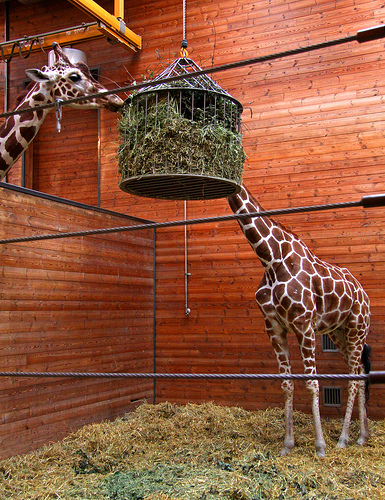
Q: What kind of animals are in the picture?
A: Giraffes.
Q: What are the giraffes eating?
A: Hay.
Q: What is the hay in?
A: A cage.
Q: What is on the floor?
A: Hay.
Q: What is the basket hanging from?
A: A wire.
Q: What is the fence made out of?
A: Metal.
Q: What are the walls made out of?
A: Wood.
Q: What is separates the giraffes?
A: A wall.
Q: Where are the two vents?
A: Behind the giraffe.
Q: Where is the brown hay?
A: On the ground.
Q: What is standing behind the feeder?
A: A giraffe.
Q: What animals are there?
A: Giraffes.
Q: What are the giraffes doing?
A: Eating.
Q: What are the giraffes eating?
A: Hay.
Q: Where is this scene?
A: Barn.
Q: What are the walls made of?
A: Wood.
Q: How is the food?
A: Hanging.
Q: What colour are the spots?
A: Brown.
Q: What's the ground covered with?
A: Hay.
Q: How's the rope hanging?
A: Straight across.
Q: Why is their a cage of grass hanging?
A: So the giraffes can eat.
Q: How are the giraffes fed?
A: From a hanging container of grass.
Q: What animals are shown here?
A: Giraffes.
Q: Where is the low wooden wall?
A: Between the giraffes.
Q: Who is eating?
A: Two giraffes.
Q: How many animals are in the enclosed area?
A: Two.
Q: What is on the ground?
A: Hay or straw.